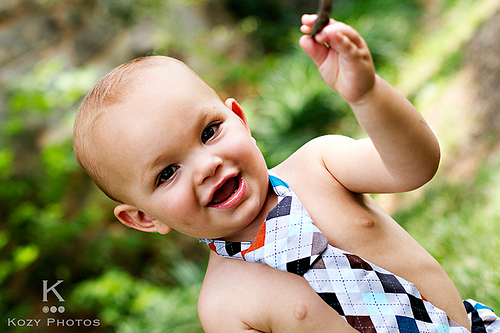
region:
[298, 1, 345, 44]
cigar in baby hand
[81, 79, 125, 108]
Blonde hair on baby head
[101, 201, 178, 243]
Left ear on baby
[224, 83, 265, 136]
Right ear on baby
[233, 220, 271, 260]
Orange color on tie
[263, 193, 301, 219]
Purple color on tie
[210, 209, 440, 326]
Baby wearing small tie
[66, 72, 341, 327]
Baby looking at camera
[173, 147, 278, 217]
Smile on baby face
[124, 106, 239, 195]
Baby has black eyes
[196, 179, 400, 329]
baby wears multicolor tie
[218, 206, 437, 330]
tie is mainly light blue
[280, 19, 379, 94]
baby holds dark brown cigar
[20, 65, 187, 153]
baby has fine brown hair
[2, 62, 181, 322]
trees in background behind baby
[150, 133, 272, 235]
baby is smiling widely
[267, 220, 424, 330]
tie has black diamond pattern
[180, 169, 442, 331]
tie has grey pattern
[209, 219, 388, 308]
tie has orange diamonds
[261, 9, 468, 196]
baby's left arm is bent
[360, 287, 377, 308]
the tie is checkered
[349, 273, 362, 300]
the tie is checkered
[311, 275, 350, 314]
the tie is checkered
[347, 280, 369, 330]
the tie is checkered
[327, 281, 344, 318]
the tie is checkered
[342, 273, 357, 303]
the tie is checkered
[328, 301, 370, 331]
the tie is checkered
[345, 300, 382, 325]
the tie is checkered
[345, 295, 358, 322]
the tie is checkered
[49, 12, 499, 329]
bald headed baby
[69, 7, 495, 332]
baby with very little hair posing for the camera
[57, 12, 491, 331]
little boy with a tie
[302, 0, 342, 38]
brown stick the little boy is holding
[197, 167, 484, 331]
colorful tie on the little boy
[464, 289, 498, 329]
diaper cover to match the tie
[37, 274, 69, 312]
emblem of the photographer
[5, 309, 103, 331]
Name of the photographer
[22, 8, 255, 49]
bushes and trees behind baby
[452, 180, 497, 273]
patch of grass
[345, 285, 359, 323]
the boy is wearing tie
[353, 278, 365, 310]
the boy is wearing tie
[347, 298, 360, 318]
the boy is wearing tie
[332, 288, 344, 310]
the boy is wearing tie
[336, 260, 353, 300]
the boy is wearing tie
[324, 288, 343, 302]
the boy is wearing tie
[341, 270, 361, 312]
the boy is wearing tie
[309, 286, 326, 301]
the boy is wearing tie